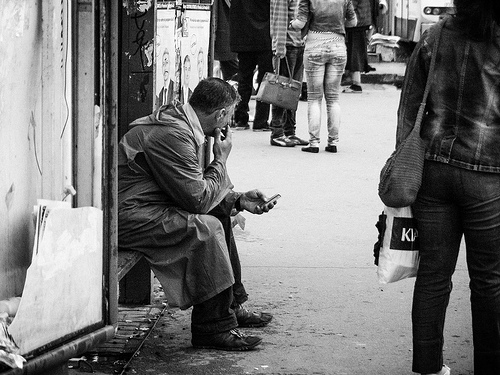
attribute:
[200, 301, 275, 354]
shoes — old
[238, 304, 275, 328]
shoe — old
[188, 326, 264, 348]
shoe — old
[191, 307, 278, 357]
shoes — black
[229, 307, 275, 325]
shoe — black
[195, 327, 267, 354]
shoe — black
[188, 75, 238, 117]
hair — dark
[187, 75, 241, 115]
hair — short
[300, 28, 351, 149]
jeans — blue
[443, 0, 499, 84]
hair — dark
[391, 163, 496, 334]
pants — black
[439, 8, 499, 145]
hair — dark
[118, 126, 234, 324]
coat — long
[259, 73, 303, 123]
purse — large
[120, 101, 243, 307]
rain coat — long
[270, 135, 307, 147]
sneakers — black and white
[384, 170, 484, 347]
jeans — tight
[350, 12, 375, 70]
skirt — black 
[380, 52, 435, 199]
bag — shoulder 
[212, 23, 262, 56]
clothes — black  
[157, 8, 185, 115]
door — truck   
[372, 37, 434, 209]
bag — plastic 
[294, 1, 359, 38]
top — black  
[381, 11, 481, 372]
jeans — tight blue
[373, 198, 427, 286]
bag — black , white 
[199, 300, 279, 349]
shoes — white tennis , black 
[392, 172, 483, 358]
pants — black 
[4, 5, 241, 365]
building — side 